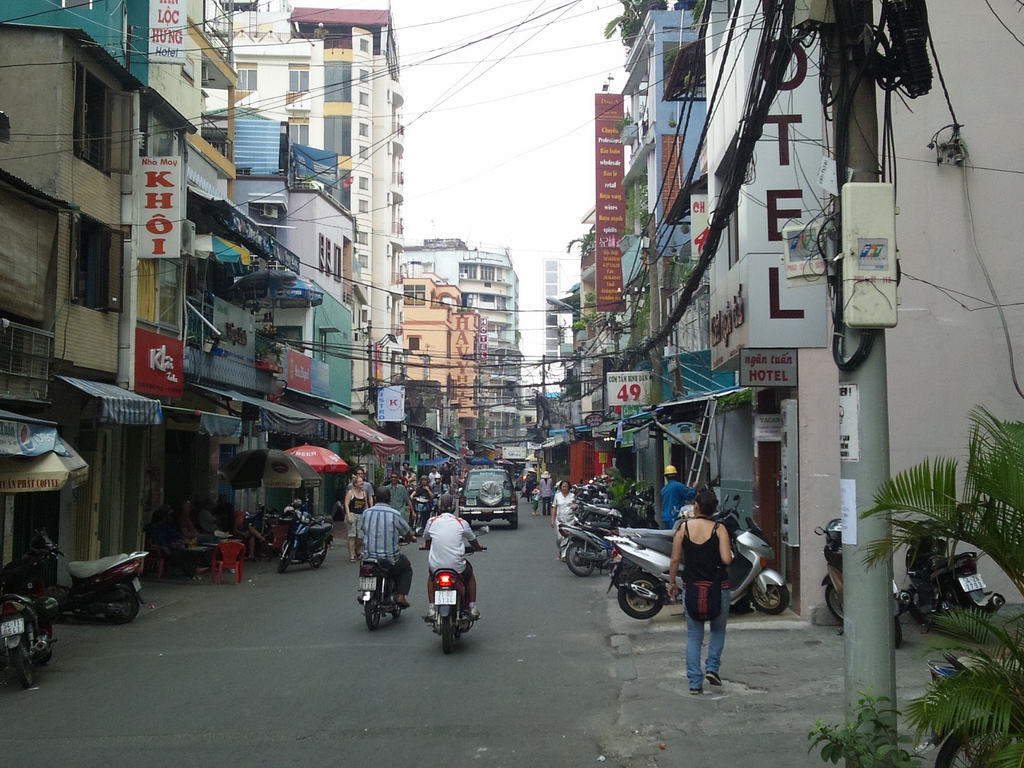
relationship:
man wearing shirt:
[419, 490, 481, 632] [422, 508, 479, 584]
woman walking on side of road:
[675, 490, 732, 697] [76, 459, 941, 760]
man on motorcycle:
[359, 487, 483, 649] [346, 556, 413, 639]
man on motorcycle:
[419, 490, 481, 632] [414, 565, 477, 652]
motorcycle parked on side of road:
[603, 510, 778, 619] [0, 452, 910, 738]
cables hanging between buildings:
[83, 7, 583, 306] [3, 1, 1023, 695]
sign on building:
[586, 87, 638, 332] [625, 1, 714, 371]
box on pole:
[818, 171, 911, 334] [820, 11, 900, 759]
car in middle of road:
[458, 468, 522, 529] [480, 535, 582, 739]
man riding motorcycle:
[419, 490, 483, 649] [433, 573, 481, 634]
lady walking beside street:
[660, 493, 733, 690] [489, 548, 621, 752]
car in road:
[458, 468, 521, 528] [124, 484, 607, 768]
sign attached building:
[133, 153, 176, 253] [26, 14, 152, 550]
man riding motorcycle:
[355, 490, 414, 613] [357, 488, 411, 628]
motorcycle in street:
[357, 488, 411, 628] [115, 617, 599, 758]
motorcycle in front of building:
[604, 509, 786, 623] [707, 18, 844, 505]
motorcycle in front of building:
[38, 535, 147, 628] [9, 10, 169, 551]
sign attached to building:
[591, 89, 628, 316] [583, 58, 752, 621]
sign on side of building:
[741, 16, 832, 349] [669, 1, 1021, 681]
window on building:
[48, 202, 126, 343] [24, 20, 171, 567]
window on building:
[39, 58, 96, 172] [26, 14, 152, 550]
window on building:
[156, 255, 214, 355] [24, 20, 171, 567]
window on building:
[140, 252, 160, 326] [9, 10, 169, 551]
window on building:
[236, 72, 253, 93] [238, 25, 403, 168]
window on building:
[276, 68, 318, 94] [243, 38, 404, 159]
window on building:
[270, 116, 305, 164] [225, 33, 400, 150]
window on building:
[309, 230, 345, 256] [284, 187, 367, 291]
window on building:
[293, 226, 354, 290] [279, 185, 360, 291]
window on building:
[362, 66, 379, 93] [351, 44, 403, 282]